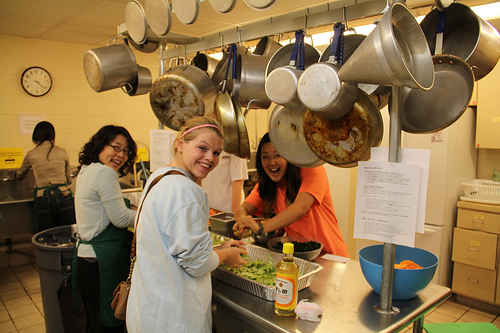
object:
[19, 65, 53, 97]
clock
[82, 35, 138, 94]
pots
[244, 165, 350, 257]
shirt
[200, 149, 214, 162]
nose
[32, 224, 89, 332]
trash can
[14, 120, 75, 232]
woman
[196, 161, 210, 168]
teeth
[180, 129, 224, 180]
face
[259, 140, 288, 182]
face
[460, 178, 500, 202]
dish strainer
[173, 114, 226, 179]
head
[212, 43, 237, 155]
pan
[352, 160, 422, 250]
papers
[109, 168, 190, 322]
purse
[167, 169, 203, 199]
shoulder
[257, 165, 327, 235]
arm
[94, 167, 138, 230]
arm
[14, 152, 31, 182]
arm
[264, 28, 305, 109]
pan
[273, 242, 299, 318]
bottle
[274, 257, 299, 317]
oil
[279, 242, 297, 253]
cap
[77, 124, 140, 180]
woman's hair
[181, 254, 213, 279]
elbow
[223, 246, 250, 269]
hand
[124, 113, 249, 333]
girl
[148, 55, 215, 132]
pan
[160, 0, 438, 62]
rack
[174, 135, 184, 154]
ear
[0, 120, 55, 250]
woman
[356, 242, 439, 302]
blue bowl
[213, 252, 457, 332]
counter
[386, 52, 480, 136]
pan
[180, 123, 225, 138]
headband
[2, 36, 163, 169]
wall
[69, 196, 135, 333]
apron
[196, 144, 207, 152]
eye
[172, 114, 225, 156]
hair